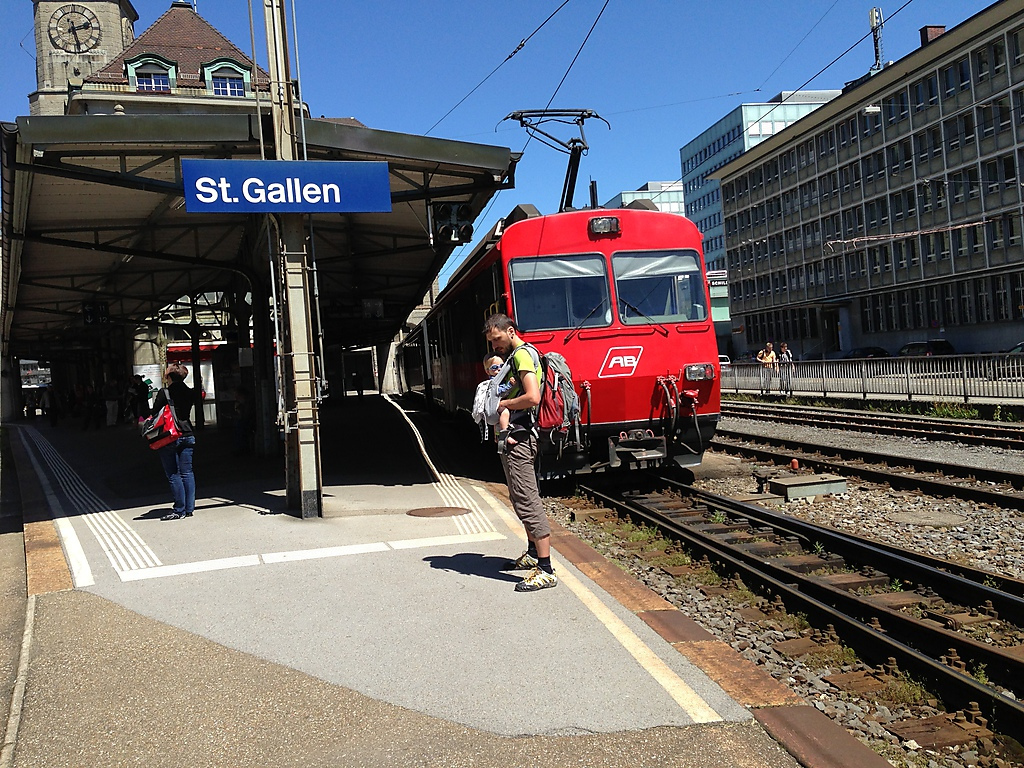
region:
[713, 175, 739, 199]
glass window on the building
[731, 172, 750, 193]
glass window on the building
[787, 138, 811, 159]
glass window on the building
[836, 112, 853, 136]
glass window on the building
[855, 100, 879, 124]
glass window on the building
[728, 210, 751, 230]
glass window on the building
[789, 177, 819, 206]
glass window on the building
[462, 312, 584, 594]
man standing by track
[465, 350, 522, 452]
man holding a todler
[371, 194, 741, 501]
train parked on tracks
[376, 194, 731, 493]
parked train is red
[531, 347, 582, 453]
backpack on man's back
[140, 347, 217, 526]
woman standing under tent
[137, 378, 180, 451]
woman wearing a handbag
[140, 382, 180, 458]
woman's handbag is large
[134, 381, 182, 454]
woman's handbag is red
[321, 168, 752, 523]
this is a train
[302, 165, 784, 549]
the train is red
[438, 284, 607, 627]
man on the platform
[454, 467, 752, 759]
yellow line on platform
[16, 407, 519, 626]
white lines on the platform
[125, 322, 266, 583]
woman on the platform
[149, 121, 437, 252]
a blue and white sign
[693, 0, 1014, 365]
building on the side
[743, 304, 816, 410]
people next to fence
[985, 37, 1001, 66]
window on a building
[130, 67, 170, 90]
window on a building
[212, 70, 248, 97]
window on a building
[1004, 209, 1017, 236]
window on a building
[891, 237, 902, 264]
window on a building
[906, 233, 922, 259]
window on a building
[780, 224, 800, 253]
window on a building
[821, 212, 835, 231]
window on a building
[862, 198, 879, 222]
window on a building